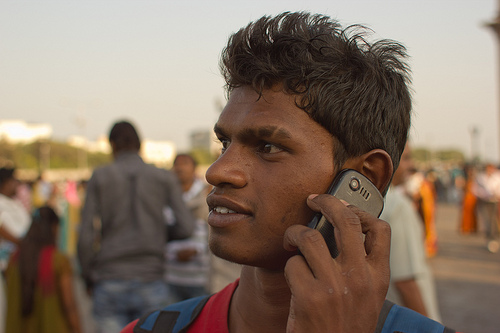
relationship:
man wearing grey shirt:
[74, 115, 187, 332] [77, 153, 195, 282]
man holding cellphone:
[114, 12, 457, 333] [308, 168, 389, 273]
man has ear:
[114, 12, 457, 333] [361, 151, 406, 178]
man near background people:
[114, 12, 457, 333] [2, 115, 496, 330]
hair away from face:
[217, 5, 341, 82] [202, 85, 322, 262]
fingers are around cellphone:
[281, 190, 392, 292] [304, 165, 384, 260]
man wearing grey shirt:
[114, 12, 457, 333] [74, 160, 199, 284]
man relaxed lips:
[114, 12, 457, 333] [201, 192, 251, 226]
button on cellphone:
[342, 172, 366, 192] [313, 172, 388, 254]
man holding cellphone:
[181, 71, 336, 279] [308, 169, 384, 258]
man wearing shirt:
[77, 120, 191, 332] [74, 147, 201, 287]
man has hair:
[114, 12, 457, 333] [214, 7, 414, 181]